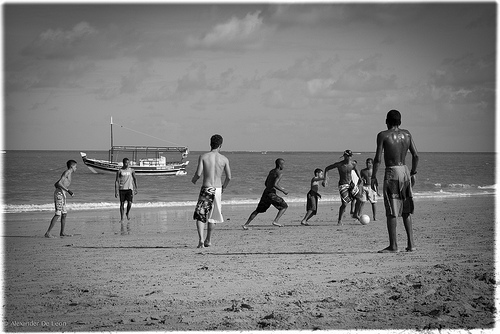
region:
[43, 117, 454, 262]
a group of boys on the beach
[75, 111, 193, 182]
a boat in the water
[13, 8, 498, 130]
clouds in the sky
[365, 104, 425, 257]
this person is watching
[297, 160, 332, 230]
the boy is grabbing his arm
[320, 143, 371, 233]
he is kicking the ball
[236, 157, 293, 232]
this person is running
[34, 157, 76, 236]
this person is leaning forward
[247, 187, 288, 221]
he is wearing dark shorts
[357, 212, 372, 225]
the ball is round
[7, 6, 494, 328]
image taken at the beach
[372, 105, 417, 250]
dark male right of image facing water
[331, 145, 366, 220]
Male directly facing dark male, kicking ball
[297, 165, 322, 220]
child to right of male kicking ball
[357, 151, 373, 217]
male to left of guy kicking ball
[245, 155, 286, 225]
male to right of child lunges forward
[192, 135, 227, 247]
light skin male facing water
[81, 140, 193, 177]
A boat is on the water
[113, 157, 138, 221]
a male with back facing water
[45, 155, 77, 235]
male sideways, next to man back facing water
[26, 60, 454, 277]
these people are playing soccer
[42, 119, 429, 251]
a friendly game of beach soccer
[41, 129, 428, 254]
soccer players on the beach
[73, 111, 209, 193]
a boat in the background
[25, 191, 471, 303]
sandy beach area for people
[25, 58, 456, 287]
this photo is in black and white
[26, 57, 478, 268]
a sunny day for playing soccer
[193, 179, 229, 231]
this guy has a towel hanging out of his shorts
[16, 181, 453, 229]
a white wave on the ocean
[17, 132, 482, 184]
the water blends into the skyline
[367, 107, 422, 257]
BLACK MALE STANDING WATCHING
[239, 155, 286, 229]
BLACK MALE RUNNING AFTER BALL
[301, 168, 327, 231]
ANOTHER BLACK MALE RUNNING AFTER BALL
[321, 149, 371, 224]
ONE BLACK MALE KICKING AFTER BALL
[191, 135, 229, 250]
STANDING WATCHING ALSO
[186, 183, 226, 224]
WITH WHITE AND BLACK TRUNK ON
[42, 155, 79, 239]
BLACK MALE WALKING AFTER BALL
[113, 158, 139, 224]
THERE ARE A FEMALE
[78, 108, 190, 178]
THERE ARE A BOAT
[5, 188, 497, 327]
PLAYING KICK BALL ON THE BEACH SIDE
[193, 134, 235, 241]
man playing on beach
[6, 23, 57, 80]
white clouds in blue sky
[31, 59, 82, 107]
white clouds in blue sky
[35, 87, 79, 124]
white clouds in blue sky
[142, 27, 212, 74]
white clouds in blue sky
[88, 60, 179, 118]
white clouds in blue sky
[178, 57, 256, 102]
white clouds in blue sky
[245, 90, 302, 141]
white clouds in blue sky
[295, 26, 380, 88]
white clouds in blue sky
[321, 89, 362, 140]
white clouds in blue sky